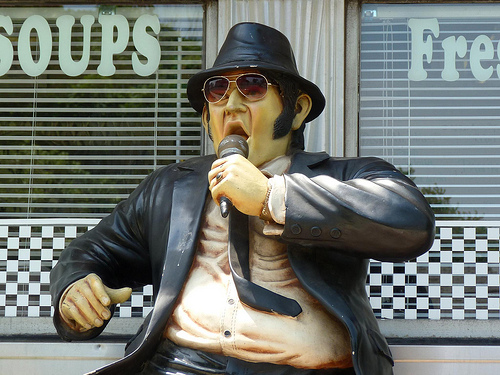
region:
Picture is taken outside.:
[20, 23, 471, 370]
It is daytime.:
[41, 20, 482, 231]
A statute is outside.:
[60, 46, 288, 371]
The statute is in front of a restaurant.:
[35, 28, 466, 230]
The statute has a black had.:
[181, 4, 335, 144]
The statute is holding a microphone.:
[192, 114, 317, 242]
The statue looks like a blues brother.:
[172, 57, 387, 368]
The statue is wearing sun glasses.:
[192, 57, 296, 132]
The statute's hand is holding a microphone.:
[204, 121, 324, 235]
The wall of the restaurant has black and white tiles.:
[12, 233, 52, 330]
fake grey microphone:
[207, 118, 262, 225]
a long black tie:
[203, 212, 303, 330]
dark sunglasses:
[188, 68, 285, 116]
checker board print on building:
[410, 230, 494, 325]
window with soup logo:
[0, 0, 182, 197]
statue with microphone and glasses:
[51, 33, 440, 372]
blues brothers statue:
[32, 20, 455, 373]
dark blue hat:
[175, 21, 339, 78]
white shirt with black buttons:
[191, 205, 335, 364]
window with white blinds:
[347, 11, 499, 209]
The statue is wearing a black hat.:
[181, 30, 323, 115]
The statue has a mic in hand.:
[208, 133, 277, 215]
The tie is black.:
[211, 172, 303, 312]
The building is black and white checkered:
[416, 223, 493, 308]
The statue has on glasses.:
[184, 68, 293, 101]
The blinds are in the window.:
[30, 56, 167, 193]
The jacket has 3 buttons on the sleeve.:
[289, 216, 347, 247]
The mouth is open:
[207, 116, 273, 151]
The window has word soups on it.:
[3, 16, 173, 96]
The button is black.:
[216, 317, 243, 342]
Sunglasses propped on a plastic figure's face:
[180, 62, 287, 117]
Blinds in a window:
[7, 27, 200, 202]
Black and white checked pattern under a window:
[6, 224, 76, 316]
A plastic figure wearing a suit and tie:
[42, 83, 419, 370]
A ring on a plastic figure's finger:
[209, 161, 236, 193]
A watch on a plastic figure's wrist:
[246, 173, 282, 233]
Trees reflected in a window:
[36, 71, 173, 179]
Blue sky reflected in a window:
[152, 2, 225, 35]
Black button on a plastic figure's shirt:
[216, 318, 236, 341]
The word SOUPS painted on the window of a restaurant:
[3, 8, 172, 116]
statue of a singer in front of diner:
[47, 20, 436, 373]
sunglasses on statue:
[198, 71, 278, 103]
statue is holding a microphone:
[215, 134, 249, 219]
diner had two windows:
[0, 0, 499, 221]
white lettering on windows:
[0, 13, 499, 81]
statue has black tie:
[227, 201, 302, 317]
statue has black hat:
[185, 20, 325, 123]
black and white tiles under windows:
[0, 225, 499, 320]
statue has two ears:
[200, 92, 312, 130]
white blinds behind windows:
[0, 17, 499, 219]